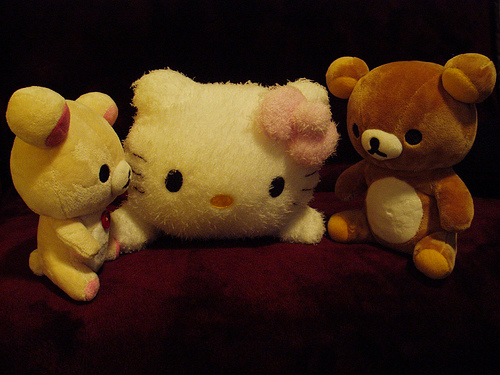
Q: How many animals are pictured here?
A: Three.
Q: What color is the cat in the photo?
A: White.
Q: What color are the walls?
A: Black.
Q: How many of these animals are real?
A: Zero.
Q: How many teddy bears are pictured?
A: Two.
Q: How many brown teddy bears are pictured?
A: One.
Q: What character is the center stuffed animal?
A: Hello kitty.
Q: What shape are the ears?
A: Round.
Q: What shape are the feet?
A: Round.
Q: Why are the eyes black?
A: Pigment.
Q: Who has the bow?
A: Hello kitty.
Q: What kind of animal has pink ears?
A: Bear.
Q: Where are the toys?
A: Red chair.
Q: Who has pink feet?
A: Left bear.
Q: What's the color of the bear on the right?
A: Brown.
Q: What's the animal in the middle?
A: Cat.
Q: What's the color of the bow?
A: Pink.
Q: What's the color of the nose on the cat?
A: Pink.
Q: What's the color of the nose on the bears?
A: Black.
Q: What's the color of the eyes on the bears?
A: Black.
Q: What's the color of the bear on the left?
A: Yellow.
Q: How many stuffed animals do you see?
A: 3.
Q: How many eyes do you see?
A: 5.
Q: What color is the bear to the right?
A: Brown and White.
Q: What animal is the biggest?
A: Middle.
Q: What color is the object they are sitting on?
A: Red.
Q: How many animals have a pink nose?
A: 1.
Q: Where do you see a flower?
A: Middle animal's ear.